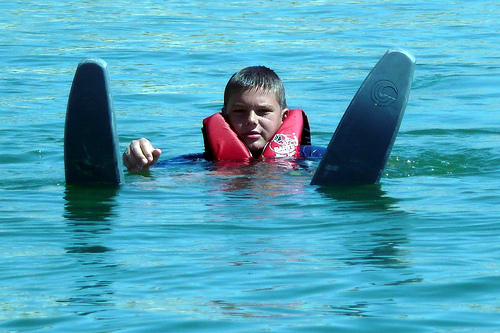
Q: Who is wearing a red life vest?
A: A man.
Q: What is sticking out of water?
A: Skis.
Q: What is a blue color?
A: Water.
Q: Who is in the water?
A: A boy.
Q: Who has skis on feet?
A: A boy.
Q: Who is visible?
A: A boy.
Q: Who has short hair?
A: A boy.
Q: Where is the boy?
A: In the water.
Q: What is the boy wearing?
A: Life jacket.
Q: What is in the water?
A: Reflection of the skies.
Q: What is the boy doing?
A: Water skiing.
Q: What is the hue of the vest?
A: Red.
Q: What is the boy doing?
A: Resting in the water.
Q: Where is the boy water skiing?
A: Ocean.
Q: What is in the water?
A: A boy.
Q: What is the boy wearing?
A: Life preserver.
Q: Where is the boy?
A: In blue waters.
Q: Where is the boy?
A: In the water.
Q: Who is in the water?
A: The boy.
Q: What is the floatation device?
A: Life jacket.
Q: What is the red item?
A: Life jacket.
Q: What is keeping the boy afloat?
A: Life jacket.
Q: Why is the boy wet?
A: He is in the water.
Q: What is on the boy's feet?
A: Water skis.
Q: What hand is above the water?
A: The boy's right one.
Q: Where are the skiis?
A: On the boy's feet.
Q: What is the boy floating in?
A: Water.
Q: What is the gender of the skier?
A: Male.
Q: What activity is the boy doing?
A: Skiing.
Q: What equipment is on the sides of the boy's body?
A: Skis.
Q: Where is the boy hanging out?
A: Water.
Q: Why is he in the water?
A: Hes skiing.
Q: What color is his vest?
A: Red.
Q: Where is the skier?
A: In the water.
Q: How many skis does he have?
A: Two.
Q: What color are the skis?
A: Black.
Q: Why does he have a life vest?
A: To float.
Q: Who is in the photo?
A: A man.